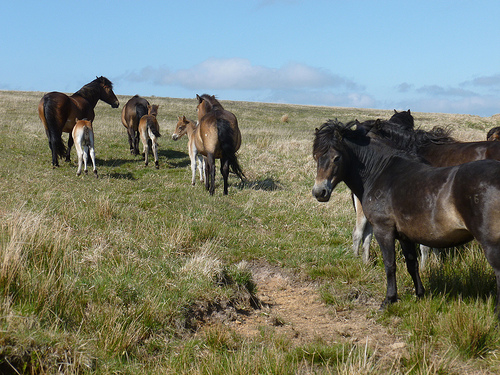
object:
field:
[0, 199, 283, 371]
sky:
[0, 2, 496, 94]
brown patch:
[181, 264, 365, 336]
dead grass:
[329, 286, 372, 321]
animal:
[310, 118, 500, 310]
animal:
[72, 118, 97, 178]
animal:
[36, 75, 119, 169]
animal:
[138, 103, 162, 169]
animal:
[171, 115, 204, 186]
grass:
[247, 114, 310, 135]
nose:
[320, 189, 327, 197]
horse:
[120, 95, 150, 155]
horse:
[391, 105, 415, 129]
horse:
[347, 118, 499, 166]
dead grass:
[267, 133, 310, 173]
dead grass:
[174, 237, 220, 280]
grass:
[0, 173, 350, 371]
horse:
[192, 94, 248, 197]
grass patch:
[257, 148, 310, 209]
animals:
[39, 73, 250, 195]